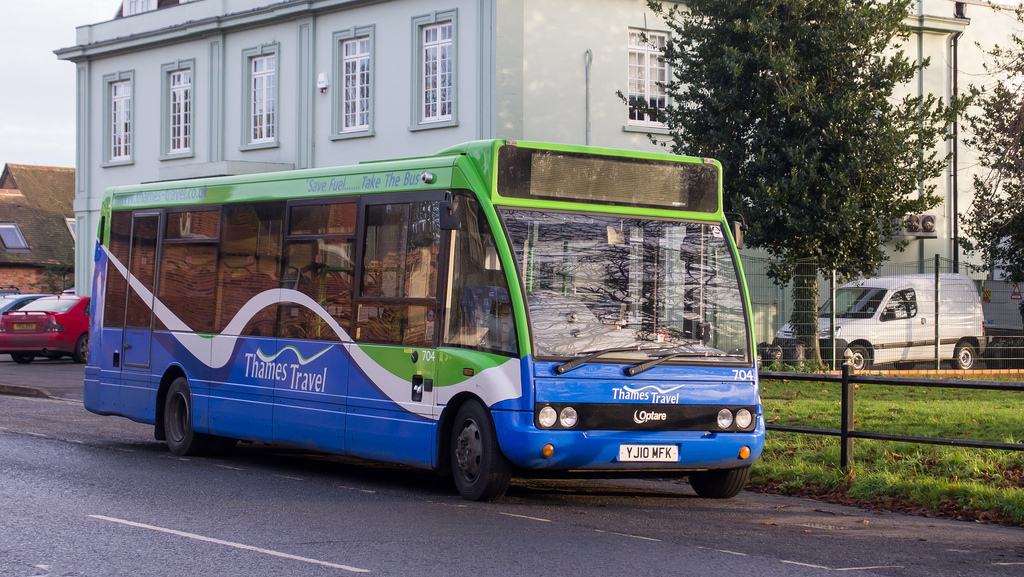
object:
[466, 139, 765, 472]
front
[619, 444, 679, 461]
license plate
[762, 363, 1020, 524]
grass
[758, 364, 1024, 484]
fence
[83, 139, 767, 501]
bus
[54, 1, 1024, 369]
building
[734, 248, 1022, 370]
fence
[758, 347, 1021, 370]
side street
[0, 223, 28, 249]
window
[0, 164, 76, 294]
house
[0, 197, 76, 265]
roof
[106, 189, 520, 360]
windows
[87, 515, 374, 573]
line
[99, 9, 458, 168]
windows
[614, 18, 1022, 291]
leaves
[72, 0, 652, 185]
wall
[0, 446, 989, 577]
street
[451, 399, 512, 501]
tire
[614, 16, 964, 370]
tree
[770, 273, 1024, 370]
car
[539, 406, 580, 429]
light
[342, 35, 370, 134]
window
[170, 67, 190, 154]
window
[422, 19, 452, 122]
window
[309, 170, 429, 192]
lettering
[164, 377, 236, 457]
tire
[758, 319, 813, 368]
bags